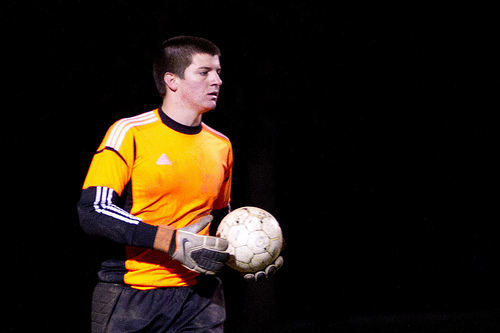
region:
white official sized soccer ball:
[217, 206, 284, 273]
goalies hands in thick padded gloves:
[155, 213, 285, 283]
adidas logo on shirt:
[158, 150, 170, 170]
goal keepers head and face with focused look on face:
[145, 34, 228, 132]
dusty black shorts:
[85, 274, 224, 331]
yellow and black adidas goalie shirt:
[79, 113, 238, 313]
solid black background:
[1, 6, 498, 331]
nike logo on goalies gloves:
[182, 234, 191, 260]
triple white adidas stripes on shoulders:
[106, 108, 155, 144]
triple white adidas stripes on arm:
[92, 188, 142, 236]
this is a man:
[78, 34, 298, 331]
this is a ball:
[213, 200, 289, 278]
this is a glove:
[158, 217, 218, 276]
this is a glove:
[230, 235, 292, 292]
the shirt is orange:
[79, 108, 236, 291]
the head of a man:
[132, 31, 232, 118]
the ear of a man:
[160, 61, 180, 96]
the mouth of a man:
[203, 86, 221, 103]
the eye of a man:
[196, 64, 213, 84]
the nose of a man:
[207, 70, 224, 92]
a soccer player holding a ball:
[55, 35, 293, 330]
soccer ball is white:
[205, 200, 290, 280]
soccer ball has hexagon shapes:
[206, 200, 282, 276]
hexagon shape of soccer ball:
[241, 225, 271, 255]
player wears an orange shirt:
[67, 32, 262, 325]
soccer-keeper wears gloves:
[70, 33, 291, 328]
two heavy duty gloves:
[154, 209, 293, 290]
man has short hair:
[117, 29, 251, 154]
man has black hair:
[121, 25, 241, 147]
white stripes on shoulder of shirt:
[74, 105, 241, 290]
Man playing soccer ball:
[80, 36, 282, 327]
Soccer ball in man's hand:
[211, 202, 281, 267]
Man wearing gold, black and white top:
[75, 100, 231, 286]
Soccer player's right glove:
[146, 220, 226, 270]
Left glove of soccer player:
[242, 247, 282, 282]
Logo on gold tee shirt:
[150, 150, 173, 170]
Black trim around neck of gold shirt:
[155, 103, 201, 133]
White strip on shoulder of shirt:
[82, 106, 158, 149]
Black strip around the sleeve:
[90, 142, 133, 173]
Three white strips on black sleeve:
[87, 183, 149, 229]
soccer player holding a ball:
[72, 28, 302, 330]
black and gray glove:
[171, 216, 230, 277]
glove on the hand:
[158, 209, 235, 281]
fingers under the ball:
[232, 253, 289, 283]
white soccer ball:
[212, 200, 288, 278]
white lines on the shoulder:
[104, 103, 157, 152]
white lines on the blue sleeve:
[94, 185, 146, 242]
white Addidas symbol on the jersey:
[154, 146, 178, 170]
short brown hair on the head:
[144, 33, 219, 91]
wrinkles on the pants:
[109, 288, 214, 332]